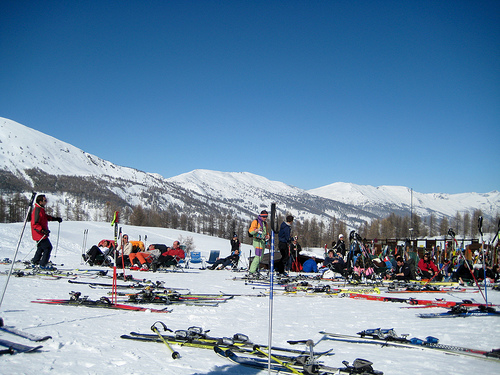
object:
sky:
[1, 0, 500, 194]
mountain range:
[0, 116, 499, 247]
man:
[30, 194, 63, 270]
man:
[206, 249, 240, 270]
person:
[129, 244, 162, 271]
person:
[82, 240, 109, 266]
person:
[231, 232, 241, 255]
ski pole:
[266, 203, 279, 373]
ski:
[129, 330, 334, 356]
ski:
[121, 334, 323, 360]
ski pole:
[151, 321, 181, 360]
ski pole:
[252, 344, 304, 375]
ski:
[29, 300, 167, 313]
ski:
[37, 298, 173, 313]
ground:
[0, 294, 157, 375]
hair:
[36, 194, 46, 203]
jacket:
[31, 202, 55, 241]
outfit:
[248, 218, 270, 273]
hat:
[259, 210, 269, 217]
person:
[152, 240, 185, 272]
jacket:
[162, 247, 185, 259]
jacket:
[148, 249, 161, 260]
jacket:
[98, 246, 110, 255]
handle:
[270, 203, 279, 234]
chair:
[185, 251, 205, 269]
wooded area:
[0, 167, 500, 251]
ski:
[0, 325, 52, 343]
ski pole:
[447, 228, 486, 303]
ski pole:
[478, 216, 489, 309]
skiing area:
[0, 220, 499, 374]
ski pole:
[119, 226, 127, 280]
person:
[115, 234, 133, 269]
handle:
[448, 228, 456, 238]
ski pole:
[54, 222, 61, 258]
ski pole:
[22, 234, 45, 261]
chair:
[172, 252, 187, 273]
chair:
[147, 244, 168, 273]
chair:
[129, 240, 144, 252]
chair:
[82, 239, 118, 267]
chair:
[206, 250, 221, 264]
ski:
[0, 338, 44, 354]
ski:
[57, 269, 112, 271]